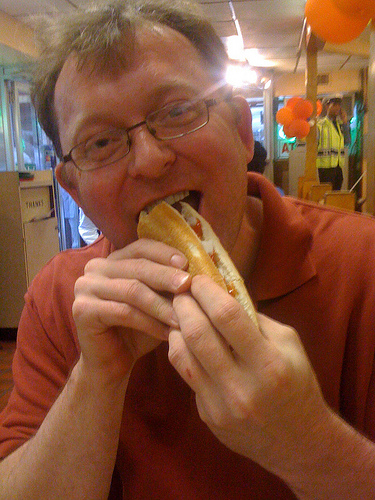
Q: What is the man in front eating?
A: Hot dog in a bun.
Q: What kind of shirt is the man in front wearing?
A: Orange polo shirt.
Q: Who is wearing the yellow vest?
A: Man in right background.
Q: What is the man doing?
A: Eating a hot dog.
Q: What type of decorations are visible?
A: Orange balloons.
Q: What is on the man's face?
A: Glasses.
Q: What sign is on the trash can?
A: Thanks.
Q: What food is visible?
A: Hot dog.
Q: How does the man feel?
A: Happy and hungry.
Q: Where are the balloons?
A: On the ceiling.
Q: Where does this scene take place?
A: In a restaurant.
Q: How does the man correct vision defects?
A: Glasses.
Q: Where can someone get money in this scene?
A: ATM.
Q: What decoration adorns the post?
A: Balloons.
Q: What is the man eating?
A: Hot dog.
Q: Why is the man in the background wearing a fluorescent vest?
A: Safety.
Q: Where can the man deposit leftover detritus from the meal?
A: Trash bin.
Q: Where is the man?
A: At an eatery place.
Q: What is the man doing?
A: Eating a sandwich.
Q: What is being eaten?
A: Hot dog.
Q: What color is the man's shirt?
A: Red.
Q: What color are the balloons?
A: Orange.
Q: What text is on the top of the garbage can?
A: Thanks.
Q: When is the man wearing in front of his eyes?
A: Glasses.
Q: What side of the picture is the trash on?
A: Left.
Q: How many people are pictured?
A: Two.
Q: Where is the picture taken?
A: In the restaurant dining room.